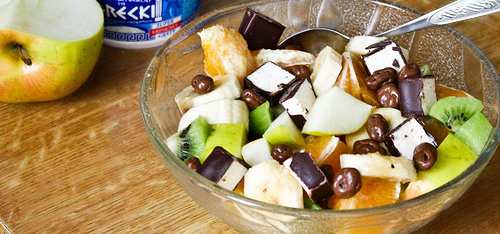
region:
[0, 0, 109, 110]
an apple on the table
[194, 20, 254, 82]
an orange piece in the salad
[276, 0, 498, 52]
a silver spoon in the bowl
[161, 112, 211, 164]
a piece of green kiwi in the salad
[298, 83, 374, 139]
a slice of apple in the salad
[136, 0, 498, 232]
a clear bowl filled with salad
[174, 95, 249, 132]
a piece of banana in the salad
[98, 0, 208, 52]
the bottom of a yogurt container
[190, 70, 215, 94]
a chocolate covered raisin in the salad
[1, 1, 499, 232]
a wooden table with food on it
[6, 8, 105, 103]
Apple cut in half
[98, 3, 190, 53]
Greek yogurt on a table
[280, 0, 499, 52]
Silver spoon in a bowl of fruit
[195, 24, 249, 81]
Piece of orange in a salad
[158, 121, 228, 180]
Piece of kiwi in a salad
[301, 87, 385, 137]
Piece of apple in a salad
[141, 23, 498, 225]
Glass bowl with fruit salad in it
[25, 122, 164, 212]
Wood table with fruit salad on it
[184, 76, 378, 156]
Mixture of fruit in a bowl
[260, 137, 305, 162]
Chocolate in a bowl of fruit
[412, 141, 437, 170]
chocolate covered raisins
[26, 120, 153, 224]
wood grain table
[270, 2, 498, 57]
stainless steel spoon in bowl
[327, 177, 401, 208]
orange slices in bowl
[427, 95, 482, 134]
light green kiwi wedges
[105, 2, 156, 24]
white lettering on blue container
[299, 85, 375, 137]
pear wedges in bowl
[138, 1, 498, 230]
clear glass bowl on table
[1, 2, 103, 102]
green apple cut in half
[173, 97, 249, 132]
sliced banana in bowl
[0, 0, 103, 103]
There is a green apple to the left of the table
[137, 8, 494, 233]
There is a fruit salad in the glass bowl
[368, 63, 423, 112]
There are brown chocolate covered raisins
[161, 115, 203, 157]
There is green kiwi in the fruit salad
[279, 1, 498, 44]
There is a silver spoon in the glass bowl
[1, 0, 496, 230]
The wooden table is brown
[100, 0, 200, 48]
The bowl of greek yogurt is blue and white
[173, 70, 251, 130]
The sliced banana is white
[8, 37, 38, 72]
The green apple has a brown stem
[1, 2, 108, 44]
The flesh of the apple is white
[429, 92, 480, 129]
sliced piece of green kiwi with black seeds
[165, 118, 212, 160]
sliced piece of green kiwi with black seeds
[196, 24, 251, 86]
sliced piece of orange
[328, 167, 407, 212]
sliced piece of orange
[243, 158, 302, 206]
sliced piece of banana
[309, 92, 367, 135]
sliced piece of apple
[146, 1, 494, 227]
large full glass bowl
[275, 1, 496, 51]
metal spoon with handle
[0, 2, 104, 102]
portion of a full yellow and red apple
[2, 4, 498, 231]
smooth wooden table top